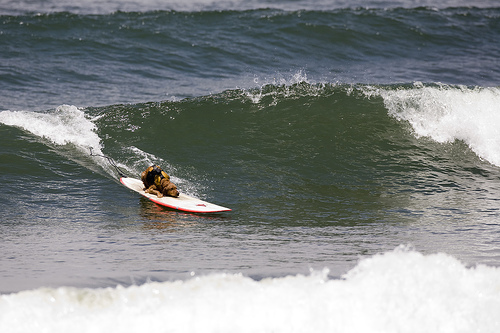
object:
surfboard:
[117, 175, 231, 213]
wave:
[0, 71, 500, 198]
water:
[0, 0, 499, 333]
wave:
[0, 0, 500, 83]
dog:
[141, 165, 180, 196]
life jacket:
[147, 165, 171, 189]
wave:
[0, 243, 499, 333]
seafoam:
[382, 83, 499, 168]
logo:
[196, 204, 207, 208]